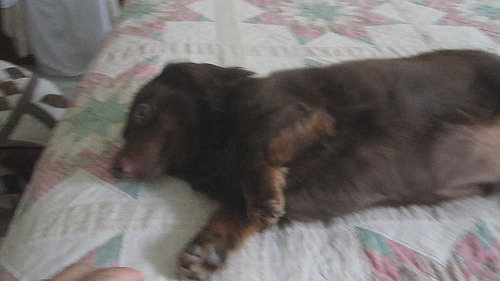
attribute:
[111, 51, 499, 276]
dog — brown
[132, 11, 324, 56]
quilt — colored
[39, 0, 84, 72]
dress — white